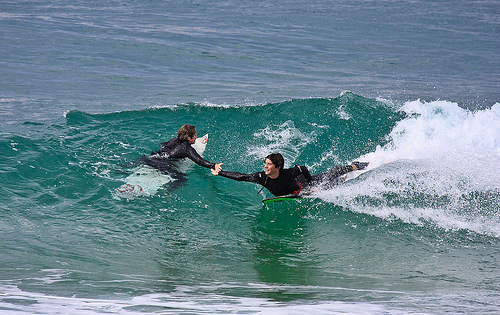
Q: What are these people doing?
A: Surfing.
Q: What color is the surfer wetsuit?
A: Black.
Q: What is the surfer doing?
A: Surfing.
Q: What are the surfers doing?
A: Holding hands.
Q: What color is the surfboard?
A: White.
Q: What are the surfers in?
A: The ocean.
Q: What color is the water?
A: Green.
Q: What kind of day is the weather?
A: Sunny.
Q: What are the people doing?
A: Surfing.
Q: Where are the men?
A: Ocean.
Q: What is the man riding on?
A: Surfboard.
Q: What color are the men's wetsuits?
A: Black.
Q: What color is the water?
A: Blue.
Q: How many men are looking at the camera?
A: None.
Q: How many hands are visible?
A: Two.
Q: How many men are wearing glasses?
A: One.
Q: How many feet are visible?
A: One.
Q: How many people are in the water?
A: Two.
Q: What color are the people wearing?
A: Black.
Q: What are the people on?
A: Surfboards.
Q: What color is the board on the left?
A: White.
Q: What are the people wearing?
A: Wetsuits.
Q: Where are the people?
A: In the ocean.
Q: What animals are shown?
A: None.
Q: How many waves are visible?
A: One.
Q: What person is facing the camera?
A: The one on the right.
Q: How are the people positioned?
A: Lying down.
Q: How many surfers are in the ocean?
A: Two.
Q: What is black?
A: Wetsuits.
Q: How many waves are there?
A: 1.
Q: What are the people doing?
A: Surfing.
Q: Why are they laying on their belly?
A: Learning.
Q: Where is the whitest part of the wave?
A: Right side wave.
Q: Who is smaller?
A: Girl left.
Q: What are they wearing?
A: Wetsuits.